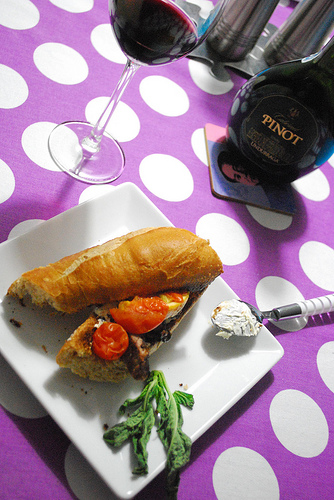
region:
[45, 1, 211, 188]
glass with liquid in it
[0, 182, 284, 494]
white plate with sandwich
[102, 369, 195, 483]
green garnish on plate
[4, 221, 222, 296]
top part of loaf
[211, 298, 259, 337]
white substance in spoon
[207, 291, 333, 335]
white handled spoon with food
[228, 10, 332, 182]
bottle of wine on table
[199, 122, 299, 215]
matt for resting glasses on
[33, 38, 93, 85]
white dot on tablecloth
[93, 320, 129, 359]
tomato on sandwich face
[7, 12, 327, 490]
large white dots on purple material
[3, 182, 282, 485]
sandwich and limp lettuce on plate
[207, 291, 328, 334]
white cream on spoon leaning on plate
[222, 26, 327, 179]
dark curved bottle of alcoholic beverage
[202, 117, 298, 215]
coaster with picture of former Chinese leader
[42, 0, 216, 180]
stemmed glass with red wine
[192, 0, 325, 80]
metal containers on metal tray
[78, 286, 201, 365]
filling of tomatoes and roasted meats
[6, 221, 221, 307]
crusty top loaf of bread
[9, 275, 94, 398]
crumbs on bottom of plate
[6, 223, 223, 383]
sandwich on a plate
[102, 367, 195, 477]
vegetable on the plate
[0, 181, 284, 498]
a square, white plate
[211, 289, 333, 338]
a spoon leaning against the plate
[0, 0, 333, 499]
purple and white tablecloth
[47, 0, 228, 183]
a wine glass on the table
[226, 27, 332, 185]
bottle of wine on the table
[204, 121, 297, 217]
Chairman Mao coaster under the bottle of wine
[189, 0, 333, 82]
metal object behind the wine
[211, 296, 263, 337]
ice cream on the spoon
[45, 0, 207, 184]
a glass of wine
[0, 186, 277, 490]
a square white plate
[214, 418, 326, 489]
a polka dotted table cloth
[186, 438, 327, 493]
a purple and white table cloth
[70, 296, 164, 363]
tomatoes on a sandwich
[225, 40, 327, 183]
a bottle of wine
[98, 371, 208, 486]
a green herb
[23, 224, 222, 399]
a sandwich on a square plate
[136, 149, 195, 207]
a white dot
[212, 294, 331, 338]
a spoon on the plate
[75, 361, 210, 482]
The garnish is green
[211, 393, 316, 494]
The table cloth has spots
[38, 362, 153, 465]
The plate is white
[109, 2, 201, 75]
The wine is dark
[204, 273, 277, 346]
The spoon has something in it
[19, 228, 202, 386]
The sandwich is toasted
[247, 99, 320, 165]
The bottle says Pinot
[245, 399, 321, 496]
The table cloth is white and purple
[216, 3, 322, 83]
Metal objects are in the back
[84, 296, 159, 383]
The sandwich has orange objects on it